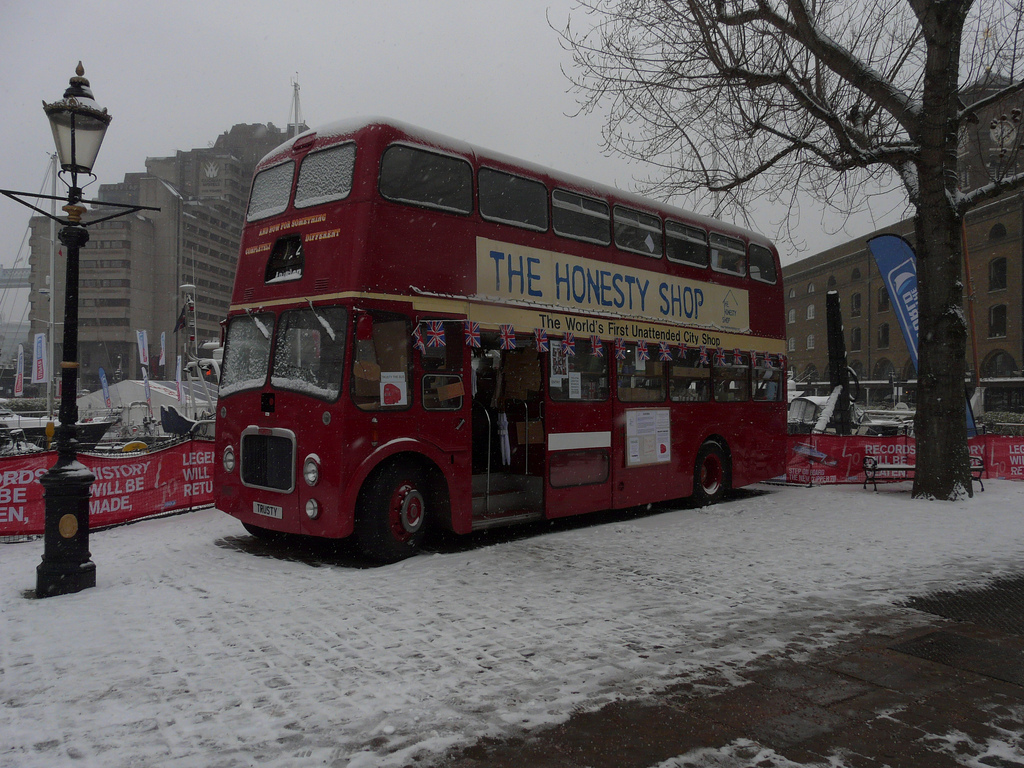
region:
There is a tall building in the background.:
[27, 36, 328, 458]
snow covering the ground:
[63, 468, 912, 624]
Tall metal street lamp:
[19, 62, 134, 626]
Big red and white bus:
[196, 130, 823, 548]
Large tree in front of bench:
[819, 13, 988, 522]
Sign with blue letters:
[427, 226, 761, 334]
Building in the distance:
[81, 84, 310, 399]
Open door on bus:
[435, 334, 638, 513]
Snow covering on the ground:
[1, 481, 1010, 756]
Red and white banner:
[2, 425, 208, 518]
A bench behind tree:
[849, 421, 992, 491]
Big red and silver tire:
[344, 453, 447, 559]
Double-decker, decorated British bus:
[170, 76, 826, 577]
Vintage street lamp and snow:
[25, 44, 128, 642]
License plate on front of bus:
[218, 458, 304, 547]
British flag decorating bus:
[401, 316, 795, 380]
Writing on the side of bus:
[467, 232, 766, 356]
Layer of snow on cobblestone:
[171, 570, 1017, 755]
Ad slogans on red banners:
[2, 411, 217, 541]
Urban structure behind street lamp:
[13, 28, 233, 383]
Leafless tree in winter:
[547, 3, 1022, 204]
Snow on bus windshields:
[234, 104, 367, 415]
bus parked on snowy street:
[215, 113, 801, 529]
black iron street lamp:
[16, 58, 141, 603]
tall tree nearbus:
[618, 3, 1021, 431]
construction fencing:
[0, 407, 239, 556]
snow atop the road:
[53, 532, 1014, 668]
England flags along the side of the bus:
[416, 310, 802, 383]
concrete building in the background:
[27, 67, 354, 482]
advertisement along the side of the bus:
[461, 228, 794, 381]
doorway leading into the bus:
[449, 306, 571, 582]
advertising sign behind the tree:
[850, 218, 997, 498]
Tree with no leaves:
[586, 1, 1001, 546]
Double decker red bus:
[207, 114, 805, 579]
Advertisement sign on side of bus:
[471, 234, 763, 326]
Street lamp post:
[27, 55, 129, 606]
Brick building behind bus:
[778, 187, 1016, 388]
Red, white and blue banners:
[0, 321, 207, 397]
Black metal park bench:
[848, 446, 981, 494]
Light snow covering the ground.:
[0, 463, 1022, 704]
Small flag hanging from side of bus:
[409, 313, 455, 361]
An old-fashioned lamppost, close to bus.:
[21, 64, 174, 638]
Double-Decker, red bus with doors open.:
[198, 105, 846, 565]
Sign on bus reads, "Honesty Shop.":
[459, 258, 767, 413]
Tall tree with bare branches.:
[648, 33, 1018, 559]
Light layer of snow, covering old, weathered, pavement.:
[59, 504, 870, 764]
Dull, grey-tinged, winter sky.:
[152, 17, 870, 223]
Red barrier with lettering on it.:
[36, 406, 1020, 537]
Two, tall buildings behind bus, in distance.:
[40, 127, 1014, 460]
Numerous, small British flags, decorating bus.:
[351, 310, 823, 435]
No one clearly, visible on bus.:
[301, 239, 918, 569]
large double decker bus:
[203, 108, 805, 574]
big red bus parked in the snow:
[200, 102, 814, 573]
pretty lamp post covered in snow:
[2, 45, 173, 606]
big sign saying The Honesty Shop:
[469, 222, 751, 339]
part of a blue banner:
[858, 223, 944, 372]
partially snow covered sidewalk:
[150, 588, 852, 760]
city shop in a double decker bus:
[191, 106, 803, 566]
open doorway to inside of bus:
[447, 292, 569, 555]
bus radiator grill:
[229, 418, 296, 499]